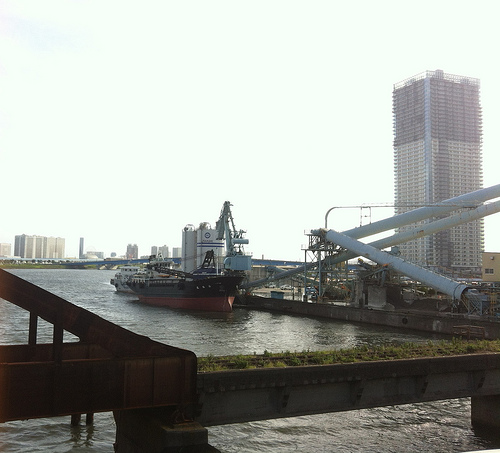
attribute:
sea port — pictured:
[65, 169, 460, 446]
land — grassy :
[211, 330, 480, 360]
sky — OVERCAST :
[5, 4, 497, 260]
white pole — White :
[323, 231, 466, 310]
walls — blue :
[181, 228, 195, 256]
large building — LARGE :
[386, 67, 484, 276]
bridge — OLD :
[197, 334, 498, 431]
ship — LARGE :
[128, 250, 243, 313]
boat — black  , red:
[135, 259, 236, 334]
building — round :
[182, 225, 221, 267]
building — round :
[392, 67, 486, 277]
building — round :
[15, 233, 64, 260]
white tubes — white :
[326, 227, 470, 301]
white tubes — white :
[338, 186, 498, 249]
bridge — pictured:
[36, 297, 267, 448]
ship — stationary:
[107, 232, 297, 354]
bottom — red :
[133, 289, 240, 319]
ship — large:
[124, 248, 246, 321]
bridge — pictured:
[0, 267, 499, 451]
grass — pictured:
[196, 336, 498, 375]